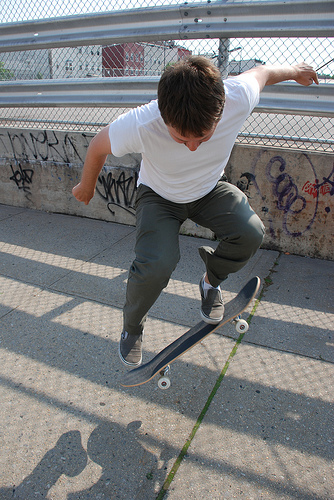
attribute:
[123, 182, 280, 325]
pants — wrinkled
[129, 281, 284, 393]
skateboard — black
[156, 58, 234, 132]
hair — brown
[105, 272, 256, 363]
shoes — black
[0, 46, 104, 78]
building — white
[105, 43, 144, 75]
building — red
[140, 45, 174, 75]
building — white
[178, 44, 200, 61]
building — red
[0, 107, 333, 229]
wall — concrete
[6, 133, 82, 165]
graffiti — black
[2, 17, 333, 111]
railing — metal, silver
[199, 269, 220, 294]
sock — white